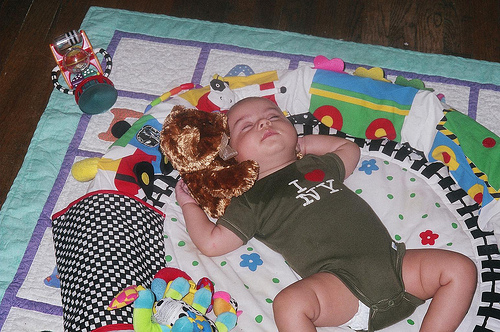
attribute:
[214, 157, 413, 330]
shirt — I love new york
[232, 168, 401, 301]
tee shirt — I love NY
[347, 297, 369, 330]
diaper — white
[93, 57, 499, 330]
infant — sleeping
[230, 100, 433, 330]
infant — very tired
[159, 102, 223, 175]
bear — stuffed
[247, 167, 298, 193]
spot — wet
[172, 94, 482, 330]
baby — on its back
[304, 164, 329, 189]
heart — red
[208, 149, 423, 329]
shirt — green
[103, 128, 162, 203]
car/blanket — blanket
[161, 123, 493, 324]
infant — sleeping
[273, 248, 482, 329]
legs — chubby, baby's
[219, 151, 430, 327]
onesie — green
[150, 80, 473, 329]
infant — sleeping